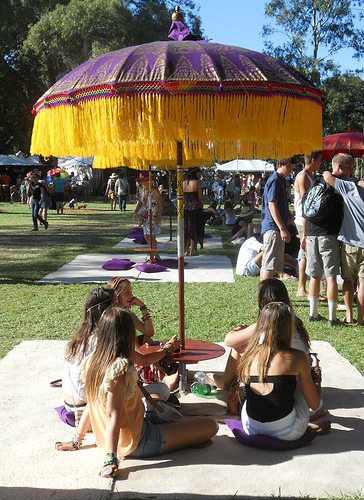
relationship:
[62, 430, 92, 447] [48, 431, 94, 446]
bracelets on wrist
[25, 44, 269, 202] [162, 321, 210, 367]
umbrella held by hand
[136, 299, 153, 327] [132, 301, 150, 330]
braclets on arm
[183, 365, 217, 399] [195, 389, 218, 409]
bottles on ground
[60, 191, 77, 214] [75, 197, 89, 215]
child petting dog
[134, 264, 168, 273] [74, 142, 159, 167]
pillow under umbrella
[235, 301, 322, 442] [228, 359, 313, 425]
girl wearing top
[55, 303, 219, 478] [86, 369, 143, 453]
girl wearing top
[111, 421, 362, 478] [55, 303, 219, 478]
shadow of girl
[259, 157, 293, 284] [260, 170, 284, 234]
man wearing shirt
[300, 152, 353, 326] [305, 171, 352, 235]
man wearing shirt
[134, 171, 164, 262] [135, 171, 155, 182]
woman wearing cowboy hat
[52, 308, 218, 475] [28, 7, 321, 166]
girl under umbrella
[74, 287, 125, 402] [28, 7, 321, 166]
girl under umbrella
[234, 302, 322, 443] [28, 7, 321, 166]
girl under umbrella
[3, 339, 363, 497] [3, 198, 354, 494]
blanket on grass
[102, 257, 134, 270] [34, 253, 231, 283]
pillow on blanket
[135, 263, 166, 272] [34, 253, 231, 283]
pillow on blanket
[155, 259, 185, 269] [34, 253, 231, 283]
pillow on blanket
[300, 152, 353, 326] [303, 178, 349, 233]
man wearing backpack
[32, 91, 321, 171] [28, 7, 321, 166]
fringe on umbrella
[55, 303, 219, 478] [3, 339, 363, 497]
girl on blanket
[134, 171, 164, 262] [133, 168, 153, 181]
woman wearing a hat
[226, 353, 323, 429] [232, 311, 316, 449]
top on woman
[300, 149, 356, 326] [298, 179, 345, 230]
man wearing backpack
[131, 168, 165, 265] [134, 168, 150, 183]
woman wearing cowboy hat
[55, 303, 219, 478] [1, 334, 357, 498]
girl sitting on slab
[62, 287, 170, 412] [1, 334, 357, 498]
girl sitting on slab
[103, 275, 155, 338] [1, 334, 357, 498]
woman sitting on slab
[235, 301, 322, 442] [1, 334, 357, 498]
girl sitting on slab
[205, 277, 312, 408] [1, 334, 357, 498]
girl sitting on slab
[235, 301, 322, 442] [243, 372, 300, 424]
girl wearing shirt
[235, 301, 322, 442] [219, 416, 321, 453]
girl sitting on pillow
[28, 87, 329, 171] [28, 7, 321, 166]
tassels are on umbrella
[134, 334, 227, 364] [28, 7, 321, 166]
table supporting umbrella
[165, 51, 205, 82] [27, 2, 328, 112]
designs are on umbrella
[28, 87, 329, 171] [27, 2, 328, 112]
tassels are on umbrella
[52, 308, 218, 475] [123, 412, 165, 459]
girl wearing shorts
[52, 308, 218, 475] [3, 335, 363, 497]
girl sitting on pad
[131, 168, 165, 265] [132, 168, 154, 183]
woman wearing hat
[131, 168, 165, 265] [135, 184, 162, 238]
woman wearing dress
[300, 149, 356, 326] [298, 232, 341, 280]
man wearing shorts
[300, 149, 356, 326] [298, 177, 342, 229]
man carrying backpack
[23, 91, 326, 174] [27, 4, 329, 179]
fringes are on umbrella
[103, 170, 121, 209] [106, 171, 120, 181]
person wearing hat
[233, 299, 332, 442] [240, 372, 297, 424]
girl wearing top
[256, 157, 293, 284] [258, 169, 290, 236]
man wearing shirt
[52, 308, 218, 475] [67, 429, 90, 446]
girl wearing bracelets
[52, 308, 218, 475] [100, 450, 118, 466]
girl wearing bracelets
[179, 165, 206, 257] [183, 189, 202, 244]
girl wearing dress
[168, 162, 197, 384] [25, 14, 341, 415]
pole for umbrella